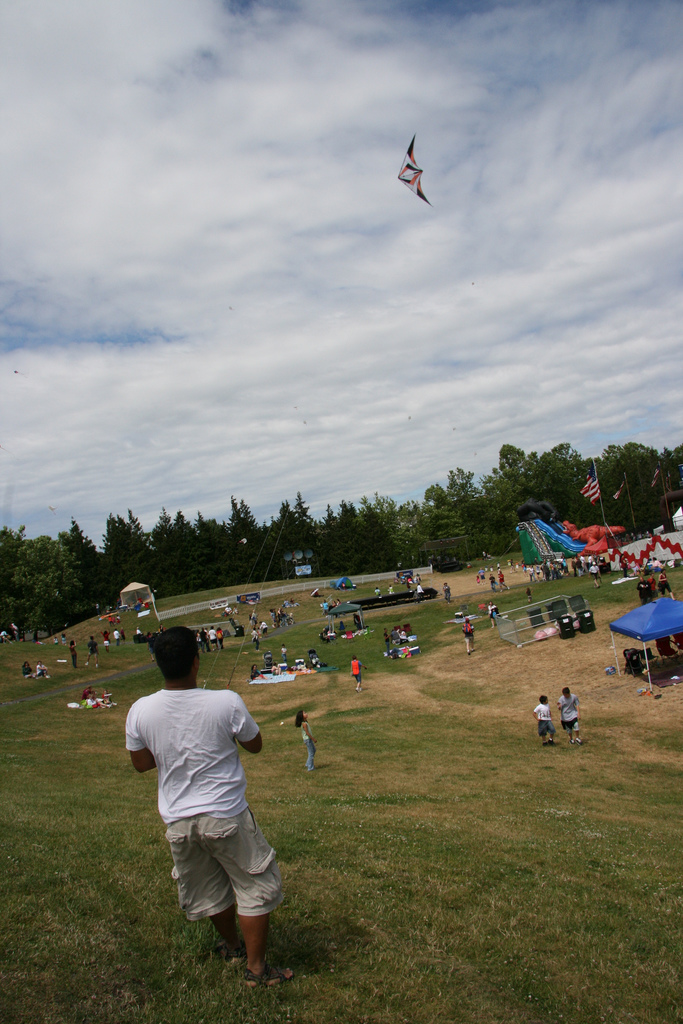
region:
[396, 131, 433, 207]
kite flying in the sky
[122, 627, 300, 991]
man is standing in the grass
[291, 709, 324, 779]
girl looking up at the sky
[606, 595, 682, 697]
blue tent is set up on grass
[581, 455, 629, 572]
American flag attached to a pole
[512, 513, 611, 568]
large blow up bounce houses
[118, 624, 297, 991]
man is flying a kite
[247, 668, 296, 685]
blanket laying on the grass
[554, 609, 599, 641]
two black garbage cans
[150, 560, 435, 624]
white fence around grassy hill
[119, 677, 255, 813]
man wearing a white tee shirt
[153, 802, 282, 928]
man wearing brown shorts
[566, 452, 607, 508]
american flag in the sky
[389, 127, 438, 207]
kite flying through the sky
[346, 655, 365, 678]
man wearing a orange shirt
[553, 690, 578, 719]
man wearing a grey shirt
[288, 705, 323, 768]
girl looking up at the kite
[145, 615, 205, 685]
man with black hair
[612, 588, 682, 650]
blue tent in the field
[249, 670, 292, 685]
blanket on the ground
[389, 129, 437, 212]
Kite in the sky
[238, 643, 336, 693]
People sitting on blankets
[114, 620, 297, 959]
Man flying a kite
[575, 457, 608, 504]
Flag on a post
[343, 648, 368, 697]
Woman in an orange vest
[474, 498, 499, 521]
green leaves on the tree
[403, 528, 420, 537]
green leaves on the tree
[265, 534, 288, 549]
green leaves on the tree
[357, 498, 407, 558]
green leaves on the tree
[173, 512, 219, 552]
green leaves on the tree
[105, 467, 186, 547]
green leaves on the tree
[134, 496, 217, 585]
green leaves on the tree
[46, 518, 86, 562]
green leaves on the tree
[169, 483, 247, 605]
green leaves on the tree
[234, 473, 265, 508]
green leaves on the tree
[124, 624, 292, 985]
Man wearing white shirt and cream shorts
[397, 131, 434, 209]
Red white and black kite flying in the sky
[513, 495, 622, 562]
large inflatable slide in background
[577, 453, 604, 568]
American Flag flying on pole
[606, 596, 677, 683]
Blue canopy with white poles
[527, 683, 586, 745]
Two boys wearing light shirts and dark shorts walking together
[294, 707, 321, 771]
Woman wearing blue jeans looking up at sky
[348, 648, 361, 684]
Woman in orange shirt walking on grass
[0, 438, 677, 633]
Row of thick green trees lining the park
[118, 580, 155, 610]
White canopy tent sitting near trees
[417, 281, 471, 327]
a white fluffy cloud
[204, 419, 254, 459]
a white fluffy cloud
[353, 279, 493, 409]
a white fluffy cloud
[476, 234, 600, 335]
a white fluffy cloud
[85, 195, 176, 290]
a white fluffy cloud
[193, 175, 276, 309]
a white fluffy cloud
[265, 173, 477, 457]
a white fluffy cloud